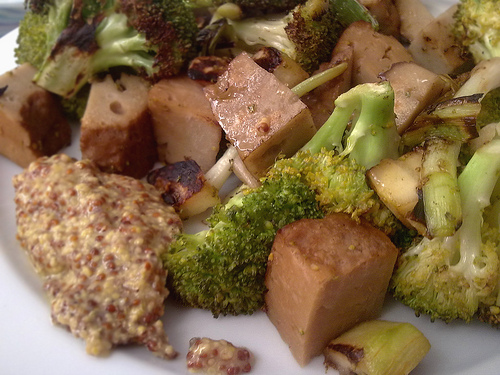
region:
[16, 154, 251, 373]
large garin mustard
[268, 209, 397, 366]
block of cooked tofu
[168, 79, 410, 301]
piece of green cooked broccoli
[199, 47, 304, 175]
piece of brown tofu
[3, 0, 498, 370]
white plate with tofu broccoli and mustard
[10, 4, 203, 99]
piece of green browned broccoli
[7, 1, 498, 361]
plate of Chinese inspired stirfry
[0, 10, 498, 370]
white rounded porcelain plate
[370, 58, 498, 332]
pieces pf fried broccoli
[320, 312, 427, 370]
green broccoli stem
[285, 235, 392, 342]
peice of meat on plate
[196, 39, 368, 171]
white peice sticking thru meat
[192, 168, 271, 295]
broccoli on the plate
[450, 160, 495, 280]
stem of the broccoli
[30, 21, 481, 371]
dish is full of meat and vegtables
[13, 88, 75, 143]
burnt on the edge of meat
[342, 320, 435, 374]
clerey that is cooked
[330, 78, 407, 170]
broccoli upside down on plate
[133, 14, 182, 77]
vegtable well done on edge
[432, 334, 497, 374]
food is on a white plate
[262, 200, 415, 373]
a piece of tofu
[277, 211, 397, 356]
a piece of tofu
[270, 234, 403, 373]
a piece of tofu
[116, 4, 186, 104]
brown part of broccoli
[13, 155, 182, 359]
A textured blob of white and brown gravy.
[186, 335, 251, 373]
A smaller blob of gravy.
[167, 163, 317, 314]
A large green chunk of broccoli touching gravy.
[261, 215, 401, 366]
The largest piece of meat along the bottom.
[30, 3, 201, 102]
The largest brownest piece of broccoli on the stem and top.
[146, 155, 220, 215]
A burnt square piece of veggie touching the top of gravy.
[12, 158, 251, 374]
Two blobs of brown and white gravy.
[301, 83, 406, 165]
Green broccoli stem sticking up on the plate.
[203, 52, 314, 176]
Piece of wet looking meat on top of the food in the middle.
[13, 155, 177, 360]
Big blob of speckled gravy.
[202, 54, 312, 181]
a chunk of grilled sausage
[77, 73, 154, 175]
a chunk of grilled sausage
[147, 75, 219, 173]
a piece of grilled sausage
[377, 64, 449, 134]
a piece of grilled sausage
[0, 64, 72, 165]
a piece of grilled sausage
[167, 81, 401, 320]
a piece of cooked broccoli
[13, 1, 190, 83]
a piece of charred broccoli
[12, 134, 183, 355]
a spoonful of brown spicy mustard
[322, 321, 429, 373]
a piece of broccoli stem